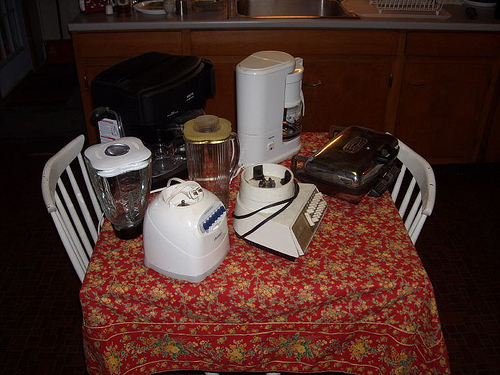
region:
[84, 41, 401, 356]
A table with appliances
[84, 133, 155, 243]
A blender with a white lid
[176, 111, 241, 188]
A blender with a yellow lid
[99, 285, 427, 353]
A red table cloth with flowers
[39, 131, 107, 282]
A white chair under table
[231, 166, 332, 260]
A blender base with a cord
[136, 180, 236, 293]
A white blender base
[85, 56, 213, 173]
A black coffee maker on a table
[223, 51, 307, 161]
A white coffee maker on a table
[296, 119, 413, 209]
A silver waffle maker on a table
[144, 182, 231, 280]
a white blender bottom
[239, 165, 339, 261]
a white and gold blender bottom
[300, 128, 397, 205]
a waffle iron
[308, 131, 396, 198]
a silver waffle iron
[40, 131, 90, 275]
back of a white chair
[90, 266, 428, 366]
a cloth table cloth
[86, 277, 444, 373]
a red and gold table cloth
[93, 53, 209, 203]
a black exproso machine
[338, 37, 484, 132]
wooden cabinets doors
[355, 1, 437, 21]
a dish stainer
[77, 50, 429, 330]
Appliances on a table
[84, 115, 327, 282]
Two blenders on a table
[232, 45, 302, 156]
Coffee maker on a table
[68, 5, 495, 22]
Counter behind table of appliances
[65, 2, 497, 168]
Island behind table of appliances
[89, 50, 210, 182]
Black specialty coffee maker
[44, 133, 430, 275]
Two white chairs at table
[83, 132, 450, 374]
Table with red patterned table cloth on it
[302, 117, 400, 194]
Waffle maker on table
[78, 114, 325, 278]
Two blenders on table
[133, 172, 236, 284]
White blender on table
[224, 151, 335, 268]
White and gold blender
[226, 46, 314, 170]
white coffee maker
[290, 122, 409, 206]
waffle iron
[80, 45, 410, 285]
Kitchen appliances on table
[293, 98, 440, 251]
waffle iron on table next to chair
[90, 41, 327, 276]
Blenders and coffee makers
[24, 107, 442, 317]
kitchen appliances on red table cloth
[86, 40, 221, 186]
Black coffee maker and blenders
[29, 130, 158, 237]
chair and blender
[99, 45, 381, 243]
small appliances on the table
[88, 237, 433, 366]
the table cloth on the table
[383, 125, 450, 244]
the chair beside the table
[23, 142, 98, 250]
the chair beside the table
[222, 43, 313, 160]
the coffee maker on the table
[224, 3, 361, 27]
the sink in the background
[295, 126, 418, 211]
the waffle iron on the table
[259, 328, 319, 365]
the flower pattern on the table cloth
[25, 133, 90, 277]
the chair is white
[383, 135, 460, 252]
the chair is white